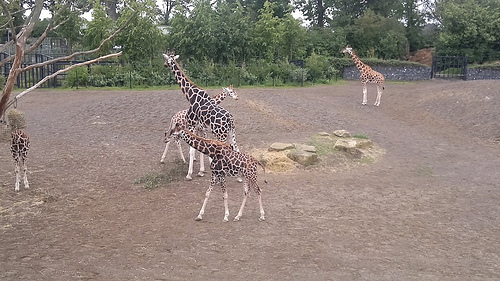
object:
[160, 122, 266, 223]
giraffes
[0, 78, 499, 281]
ground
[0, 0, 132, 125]
tree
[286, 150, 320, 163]
rocks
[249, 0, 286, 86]
trees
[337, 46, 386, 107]
giraffe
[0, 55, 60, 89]
gate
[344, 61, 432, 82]
wall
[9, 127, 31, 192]
baby giraffe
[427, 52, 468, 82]
fence gate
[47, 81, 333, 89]
grass